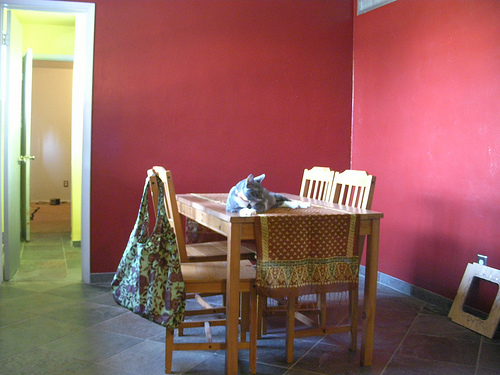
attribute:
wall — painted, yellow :
[2, 9, 77, 241]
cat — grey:
[222, 168, 315, 220]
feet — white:
[234, 195, 315, 219]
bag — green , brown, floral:
[101, 162, 196, 330]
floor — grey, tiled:
[0, 226, 497, 371]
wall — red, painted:
[94, 1, 351, 281]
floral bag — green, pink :
[108, 161, 189, 331]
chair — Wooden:
[182, 239, 264, 336]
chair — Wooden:
[241, 164, 334, 328]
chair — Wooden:
[260, 171, 377, 368]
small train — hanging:
[102, 164, 187, 327]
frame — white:
[1, 2, 96, 286]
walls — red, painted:
[97, 5, 498, 312]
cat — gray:
[226, 175, 311, 216]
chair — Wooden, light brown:
[140, 162, 260, 374]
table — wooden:
[166, 190, 381, 369]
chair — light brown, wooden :
[321, 168, 374, 207]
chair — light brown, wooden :
[292, 163, 338, 195]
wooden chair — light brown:
[130, 172, 224, 291]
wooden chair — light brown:
[150, 172, 215, 272]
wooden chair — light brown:
[329, 167, 372, 210]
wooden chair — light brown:
[294, 162, 339, 208]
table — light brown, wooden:
[166, 187, 408, 364]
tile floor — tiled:
[4, 281, 414, 373]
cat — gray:
[222, 163, 313, 222]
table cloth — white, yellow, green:
[252, 209, 368, 297]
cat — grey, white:
[225, 161, 277, 221]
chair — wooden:
[145, 167, 255, 371]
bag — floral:
[108, 166, 186, 327]